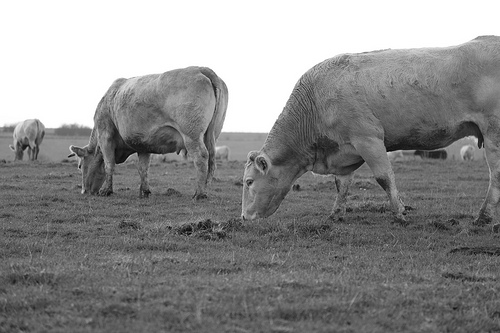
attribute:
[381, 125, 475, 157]
underneath — wet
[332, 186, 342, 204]
knee — wet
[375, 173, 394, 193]
knee — wet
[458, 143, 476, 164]
cow — white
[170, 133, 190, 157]
udder — wet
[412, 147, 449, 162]
cow — black